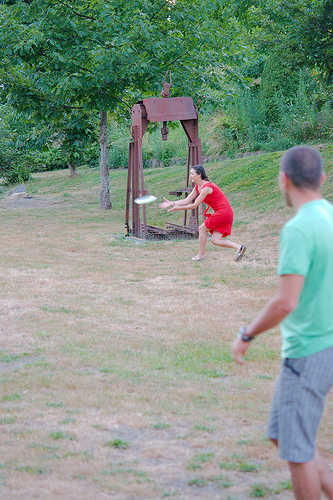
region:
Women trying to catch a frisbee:
[108, 150, 253, 262]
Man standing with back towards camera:
[230, 136, 330, 496]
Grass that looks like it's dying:
[1, 140, 331, 499]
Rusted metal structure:
[122, 67, 210, 244]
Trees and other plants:
[0, 1, 331, 187]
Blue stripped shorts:
[263, 351, 331, 462]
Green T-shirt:
[274, 193, 332, 362]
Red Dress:
[190, 181, 237, 238]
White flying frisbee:
[127, 190, 163, 209]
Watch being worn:
[239, 327, 257, 346]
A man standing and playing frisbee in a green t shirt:
[126, 141, 329, 498]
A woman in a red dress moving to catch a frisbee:
[101, 150, 257, 254]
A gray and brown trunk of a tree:
[74, 106, 121, 208]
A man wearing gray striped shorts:
[272, 132, 314, 473]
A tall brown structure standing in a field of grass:
[112, 77, 212, 260]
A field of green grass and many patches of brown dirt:
[45, 291, 164, 437]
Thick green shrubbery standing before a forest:
[220, 54, 329, 147]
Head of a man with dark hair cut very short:
[271, 134, 328, 202]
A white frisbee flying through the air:
[121, 187, 162, 219]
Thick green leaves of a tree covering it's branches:
[4, 5, 219, 87]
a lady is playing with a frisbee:
[59, 68, 249, 275]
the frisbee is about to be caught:
[117, 163, 234, 251]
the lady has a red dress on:
[162, 164, 239, 246]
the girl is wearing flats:
[189, 243, 248, 266]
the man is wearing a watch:
[235, 325, 258, 344]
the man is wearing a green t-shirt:
[278, 199, 331, 355]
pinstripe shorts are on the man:
[269, 345, 332, 463]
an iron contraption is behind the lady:
[112, 70, 210, 245]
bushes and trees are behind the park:
[24, 37, 332, 221]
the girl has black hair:
[185, 164, 208, 187]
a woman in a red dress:
[157, 165, 247, 261]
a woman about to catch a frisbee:
[158, 165, 248, 260]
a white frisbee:
[131, 192, 157, 206]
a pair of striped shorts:
[262, 346, 331, 463]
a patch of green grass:
[102, 436, 128, 449]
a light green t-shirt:
[275, 197, 332, 359]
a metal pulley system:
[123, 69, 196, 243]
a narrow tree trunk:
[94, 111, 116, 205]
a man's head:
[277, 145, 325, 201]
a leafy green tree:
[12, 2, 184, 207]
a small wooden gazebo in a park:
[124, 68, 203, 237]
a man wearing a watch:
[237, 328, 256, 343]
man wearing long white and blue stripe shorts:
[267, 344, 332, 464]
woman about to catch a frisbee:
[125, 165, 246, 262]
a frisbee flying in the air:
[133, 193, 157, 208]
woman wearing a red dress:
[194, 183, 233, 235]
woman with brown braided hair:
[190, 165, 212, 185]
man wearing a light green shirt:
[278, 199, 332, 361]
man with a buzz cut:
[278, 146, 325, 189]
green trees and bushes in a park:
[2, 0, 328, 208]